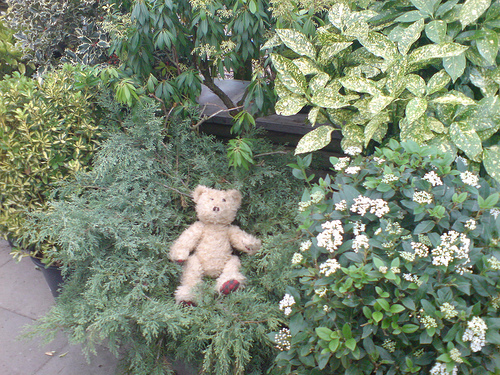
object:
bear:
[166, 184, 263, 308]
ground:
[0, 233, 197, 374]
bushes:
[2, 1, 315, 305]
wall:
[170, 118, 346, 152]